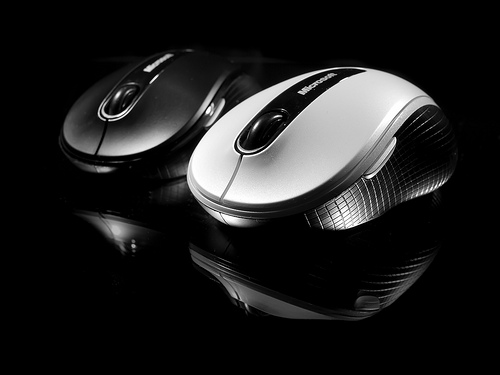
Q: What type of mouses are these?
A: Microsoft.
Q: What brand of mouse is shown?
A: Microsoft.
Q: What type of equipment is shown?
A: Computer mouses.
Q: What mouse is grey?
A: The right one.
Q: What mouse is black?
A: The left one.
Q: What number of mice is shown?
A: Two.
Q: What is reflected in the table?
A: Mice.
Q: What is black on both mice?
A: Buttons.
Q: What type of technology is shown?
A: Computer.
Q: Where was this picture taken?
A: A studio.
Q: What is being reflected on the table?
A: The mouse.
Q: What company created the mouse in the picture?
A: Microsoft.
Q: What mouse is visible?
A: An optical mouse.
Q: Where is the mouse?
A: On a shiny surface.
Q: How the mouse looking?
A: Silver and black.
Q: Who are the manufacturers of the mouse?
A: Microsoft.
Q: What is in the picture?
A: Two mouses.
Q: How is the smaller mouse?
A: It is black.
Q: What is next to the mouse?
A: A small black mouse.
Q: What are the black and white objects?
A: A mouse.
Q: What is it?
A: Mouse.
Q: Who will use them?
A: People.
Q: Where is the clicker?
A: On the mouse.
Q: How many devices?
A: 2.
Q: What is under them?
A: Reflection.